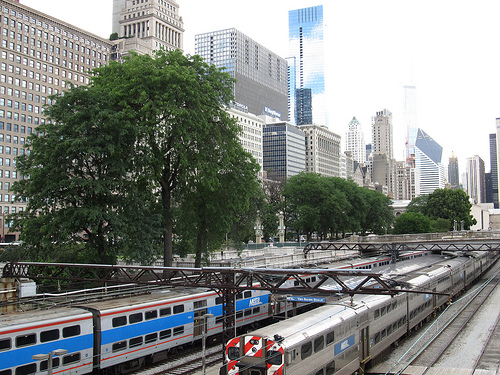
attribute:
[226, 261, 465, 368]
train — parked, metal, long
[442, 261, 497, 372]
tracks — metal, empty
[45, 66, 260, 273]
tree — green, near street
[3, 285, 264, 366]
cars — silver, double-decker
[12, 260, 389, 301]
supports — overhead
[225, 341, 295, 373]
stripes — white, red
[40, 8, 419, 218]
buildings — in city, tall, windowed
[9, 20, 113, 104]
windows — glass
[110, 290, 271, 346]
line — blue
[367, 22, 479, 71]
clouds — white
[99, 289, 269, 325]
stripe — blue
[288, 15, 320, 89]
sky — in building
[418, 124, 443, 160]
roof — sloped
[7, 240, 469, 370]
trains — passenger cars